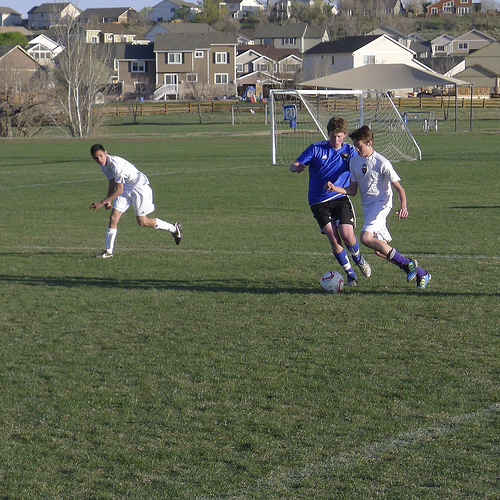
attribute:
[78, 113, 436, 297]
children — slide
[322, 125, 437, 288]
players — for soccer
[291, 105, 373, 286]
players — for soccer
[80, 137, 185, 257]
players — for soccer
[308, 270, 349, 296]
ball — for soccer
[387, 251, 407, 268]
socks — purple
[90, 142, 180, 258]
players — for soccer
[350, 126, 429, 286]
players — for soccer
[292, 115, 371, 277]
players — for soccer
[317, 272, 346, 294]
soccer ball — white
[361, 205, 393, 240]
shorts — white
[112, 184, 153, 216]
shorts — white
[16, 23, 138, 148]
tree — birch, leafless, growing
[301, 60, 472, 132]
awning — tan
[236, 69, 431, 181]
goal — white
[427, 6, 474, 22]
house — orange-red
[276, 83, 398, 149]
mesh cage — white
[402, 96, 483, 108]
fence — wooden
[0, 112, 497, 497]
field — for play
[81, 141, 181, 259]
player — for soccer, in white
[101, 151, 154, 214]
uniform — white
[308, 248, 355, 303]
ball — red, white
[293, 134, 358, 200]
t-shirt — blue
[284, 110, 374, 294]
player — for soccer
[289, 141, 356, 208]
jersey — blue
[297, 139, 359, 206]
uniform — blue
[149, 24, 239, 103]
house — tan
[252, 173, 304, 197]
field — for soccer, grass, green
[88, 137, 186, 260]
soccer player — in white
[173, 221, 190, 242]
cleats — black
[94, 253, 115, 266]
cleats — black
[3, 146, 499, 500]
field — for soccer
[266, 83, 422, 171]
goal — for soccer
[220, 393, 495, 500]
line — white, faded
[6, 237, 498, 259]
line — white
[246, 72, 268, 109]
playground — children's